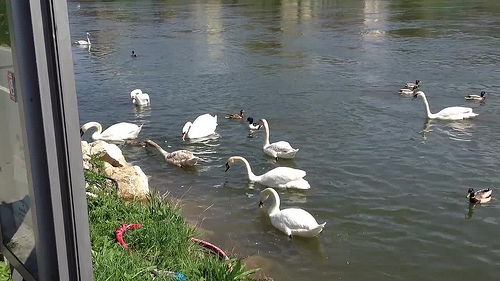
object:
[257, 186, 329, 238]
swan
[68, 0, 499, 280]
water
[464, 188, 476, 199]
head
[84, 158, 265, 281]
grass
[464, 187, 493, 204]
duck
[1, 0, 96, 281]
building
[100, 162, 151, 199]
rock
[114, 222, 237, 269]
hose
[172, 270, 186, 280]
object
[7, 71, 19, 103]
sticker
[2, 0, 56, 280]
glass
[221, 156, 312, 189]
bird